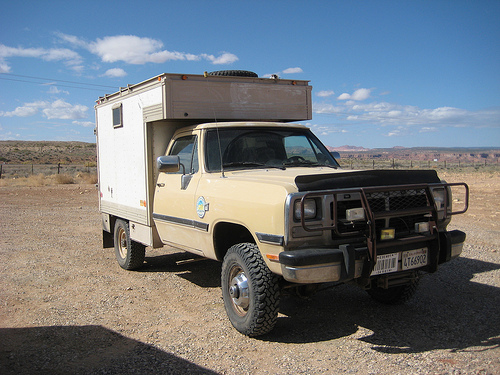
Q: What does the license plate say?
A: 4T66902.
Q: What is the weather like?
A: Sunny.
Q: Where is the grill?
A: Front of vehicle.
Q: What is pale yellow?
A: Truck.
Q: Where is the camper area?
A: On the back of truck.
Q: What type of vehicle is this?
A: Pick up truck.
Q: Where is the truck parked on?
A: Gravel.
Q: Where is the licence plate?
A: Lower front.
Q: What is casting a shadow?
A: Truck.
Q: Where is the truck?
A: Middle of desert.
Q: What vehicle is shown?
A: Truck.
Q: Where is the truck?
A: In the desert.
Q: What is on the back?
A: A camper.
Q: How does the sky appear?
A: Partly cloudy.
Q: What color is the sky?
A: Blue.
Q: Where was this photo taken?
A: On a desert.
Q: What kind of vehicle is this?
A: A truck.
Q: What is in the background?
A: Buildings.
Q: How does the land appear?
A: Rocky.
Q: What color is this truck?
A: Yellow.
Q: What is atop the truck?
A: A wheel.